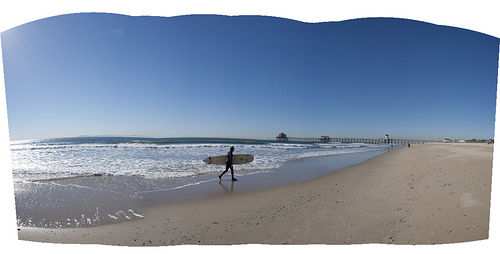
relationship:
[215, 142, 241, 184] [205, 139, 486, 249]
man walking toward beach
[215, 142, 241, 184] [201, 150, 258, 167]
man carrying surfboard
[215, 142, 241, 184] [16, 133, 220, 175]
man leaving ocean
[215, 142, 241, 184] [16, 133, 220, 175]
man leaving water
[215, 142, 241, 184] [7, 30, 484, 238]
surfer finishing day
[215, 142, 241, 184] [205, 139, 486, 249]
surfer headed toward sand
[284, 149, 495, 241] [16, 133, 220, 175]
edge on ocean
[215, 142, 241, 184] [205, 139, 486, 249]
surfer walking on beach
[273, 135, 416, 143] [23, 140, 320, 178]
pier behind waves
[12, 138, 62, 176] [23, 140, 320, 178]
reflection shining on waves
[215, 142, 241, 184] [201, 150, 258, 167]
man holding surfboard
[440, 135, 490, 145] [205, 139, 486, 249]
houses alongside beach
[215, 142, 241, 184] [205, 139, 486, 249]
man walking on sand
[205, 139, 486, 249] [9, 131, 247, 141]
beach seen horizon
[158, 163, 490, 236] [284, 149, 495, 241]
shore has edge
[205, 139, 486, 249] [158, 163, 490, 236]
beach seen a part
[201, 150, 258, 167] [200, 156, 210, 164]
board has a tip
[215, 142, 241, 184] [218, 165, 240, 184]
man seen legs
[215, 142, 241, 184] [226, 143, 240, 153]
man seen head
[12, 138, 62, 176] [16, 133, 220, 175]
reflection of sun on water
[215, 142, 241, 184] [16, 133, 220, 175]
surfer walking in water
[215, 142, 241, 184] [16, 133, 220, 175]
man walking in water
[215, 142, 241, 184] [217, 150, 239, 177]
man wearing wet suit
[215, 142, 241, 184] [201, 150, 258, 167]
man carrying surf board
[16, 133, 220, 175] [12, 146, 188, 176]
ocean has white foam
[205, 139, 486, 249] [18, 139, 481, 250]
sand along beach